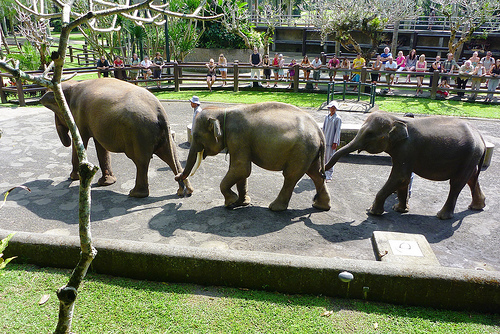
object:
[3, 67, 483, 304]
enclosure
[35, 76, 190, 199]
elephant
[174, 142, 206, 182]
tusk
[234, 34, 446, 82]
visitor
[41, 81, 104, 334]
tree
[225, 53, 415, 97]
fence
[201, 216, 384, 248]
platform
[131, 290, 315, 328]
area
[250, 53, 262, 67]
top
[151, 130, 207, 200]
trunk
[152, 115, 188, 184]
tail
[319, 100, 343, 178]
man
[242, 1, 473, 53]
building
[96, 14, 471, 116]
background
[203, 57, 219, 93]
person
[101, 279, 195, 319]
grass